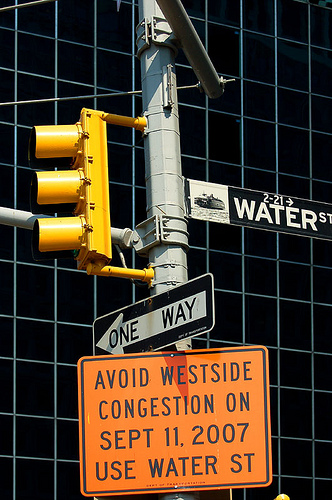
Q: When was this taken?
A: Daytime.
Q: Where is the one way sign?
A: Under the traffic light.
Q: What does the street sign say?
A: Water st.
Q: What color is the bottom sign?
A: Orange.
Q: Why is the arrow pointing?
A: You can only go that way.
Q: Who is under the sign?
A: No one.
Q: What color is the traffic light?
A: Yellow.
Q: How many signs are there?
A: Three.